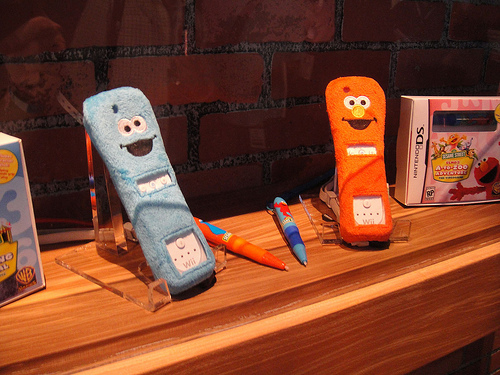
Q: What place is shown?
A: It is a display.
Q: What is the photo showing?
A: It is showing a display.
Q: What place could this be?
A: It is a display.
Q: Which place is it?
A: It is a display.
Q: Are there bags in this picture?
A: No, there are no bags.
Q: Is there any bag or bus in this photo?
A: No, there are no bags or buses.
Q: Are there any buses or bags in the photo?
A: No, there are no bags or buses.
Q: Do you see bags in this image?
A: No, there are no bags.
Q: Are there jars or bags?
A: No, there are no bags or jars.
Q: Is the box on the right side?
A: Yes, the box is on the right of the image.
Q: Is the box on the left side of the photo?
A: No, the box is on the right of the image.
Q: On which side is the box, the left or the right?
A: The box is on the right of the image.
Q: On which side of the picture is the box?
A: The box is on the right of the image.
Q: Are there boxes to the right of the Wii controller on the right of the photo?
A: Yes, there is a box to the right of the Wii remotes.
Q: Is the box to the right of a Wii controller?
A: Yes, the box is to the right of a Wii controller.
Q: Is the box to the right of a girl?
A: No, the box is to the right of a Wii controller.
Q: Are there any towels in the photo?
A: No, there are no towels.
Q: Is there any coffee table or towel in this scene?
A: No, there are no towels or coffee tables.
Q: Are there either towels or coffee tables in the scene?
A: No, there are no towels or coffee tables.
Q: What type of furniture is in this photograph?
A: The furniture is a shelf.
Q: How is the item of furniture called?
A: The piece of furniture is a shelf.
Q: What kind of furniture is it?
A: The piece of furniture is a shelf.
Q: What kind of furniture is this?
A: This is a shelf.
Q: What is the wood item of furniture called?
A: The piece of furniture is a shelf.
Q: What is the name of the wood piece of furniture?
A: The piece of furniture is a shelf.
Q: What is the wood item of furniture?
A: The piece of furniture is a shelf.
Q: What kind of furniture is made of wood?
A: The furniture is a shelf.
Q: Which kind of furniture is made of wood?
A: The furniture is a shelf.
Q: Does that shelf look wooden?
A: Yes, the shelf is wooden.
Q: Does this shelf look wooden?
A: Yes, the shelf is wooden.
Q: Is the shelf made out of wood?
A: Yes, the shelf is made of wood.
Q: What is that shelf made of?
A: The shelf is made of wood.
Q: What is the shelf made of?
A: The shelf is made of wood.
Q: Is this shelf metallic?
A: No, the shelf is wooden.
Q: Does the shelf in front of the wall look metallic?
A: No, the shelf is wooden.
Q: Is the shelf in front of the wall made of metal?
A: No, the shelf is made of wood.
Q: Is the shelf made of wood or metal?
A: The shelf is made of wood.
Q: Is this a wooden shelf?
A: Yes, this is a wooden shelf.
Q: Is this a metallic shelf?
A: No, this is a wooden shelf.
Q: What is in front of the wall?
A: The shelf is in front of the wall.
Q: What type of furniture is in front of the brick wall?
A: The piece of furniture is a shelf.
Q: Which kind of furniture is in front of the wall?
A: The piece of furniture is a shelf.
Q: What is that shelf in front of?
A: The shelf is in front of the wall.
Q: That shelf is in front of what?
A: The shelf is in front of the wall.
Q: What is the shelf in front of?
A: The shelf is in front of the wall.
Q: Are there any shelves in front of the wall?
A: Yes, there is a shelf in front of the wall.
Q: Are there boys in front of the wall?
A: No, there is a shelf in front of the wall.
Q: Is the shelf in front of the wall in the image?
A: Yes, the shelf is in front of the wall.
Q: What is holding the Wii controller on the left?
A: The shelf is holding the Wii controller.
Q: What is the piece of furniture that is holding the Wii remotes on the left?
A: The piece of furniture is a shelf.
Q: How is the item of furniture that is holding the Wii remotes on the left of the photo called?
A: The piece of furniture is a shelf.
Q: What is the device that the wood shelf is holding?
A: The device is a Wii controller.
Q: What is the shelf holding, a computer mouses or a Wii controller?
A: The shelf is holding a Wii controller.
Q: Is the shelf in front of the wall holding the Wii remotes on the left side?
A: Yes, the shelf is holding the Wii controller.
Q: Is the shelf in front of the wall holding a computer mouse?
A: No, the shelf is holding the Wii controller.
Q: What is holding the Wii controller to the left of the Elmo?
A: The shelf is holding the Wii controller.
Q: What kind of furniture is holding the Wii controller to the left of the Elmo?
A: The piece of furniture is a shelf.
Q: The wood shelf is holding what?
A: The shelf is holding the Wii controller.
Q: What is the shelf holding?
A: The shelf is holding the Wii controller.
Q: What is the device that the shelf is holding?
A: The device is a Wii controller.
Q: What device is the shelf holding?
A: The shelf is holding the Wii remotes.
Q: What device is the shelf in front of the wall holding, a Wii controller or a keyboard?
A: The shelf is holding a Wii controller.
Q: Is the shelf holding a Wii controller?
A: Yes, the shelf is holding a Wii controller.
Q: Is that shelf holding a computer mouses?
A: No, the shelf is holding a Wii controller.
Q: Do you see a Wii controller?
A: Yes, there is a Wii controller.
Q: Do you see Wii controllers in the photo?
A: Yes, there is a Wii controller.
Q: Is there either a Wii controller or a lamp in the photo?
A: Yes, there is a Wii controller.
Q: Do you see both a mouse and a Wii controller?
A: No, there is a Wii controller but no computer mice.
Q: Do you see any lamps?
A: No, there are no lamps.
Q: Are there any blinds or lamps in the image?
A: No, there are no lamps or blinds.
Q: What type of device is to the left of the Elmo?
A: The device is a Wii controller.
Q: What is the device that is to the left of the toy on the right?
A: The device is a Wii controller.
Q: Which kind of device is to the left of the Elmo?
A: The device is a Wii controller.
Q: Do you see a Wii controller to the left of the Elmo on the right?
A: Yes, there is a Wii controller to the left of the Elmo.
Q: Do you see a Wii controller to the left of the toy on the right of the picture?
A: Yes, there is a Wii controller to the left of the Elmo.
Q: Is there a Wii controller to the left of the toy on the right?
A: Yes, there is a Wii controller to the left of the Elmo.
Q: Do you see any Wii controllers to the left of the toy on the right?
A: Yes, there is a Wii controller to the left of the Elmo.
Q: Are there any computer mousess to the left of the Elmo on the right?
A: No, there is a Wii controller to the left of the Elmo.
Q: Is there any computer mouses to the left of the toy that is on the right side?
A: No, there is a Wii controller to the left of the Elmo.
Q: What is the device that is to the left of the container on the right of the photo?
A: The device is a Wii controller.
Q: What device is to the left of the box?
A: The device is a Wii controller.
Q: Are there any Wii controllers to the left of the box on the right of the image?
A: Yes, there is a Wii controller to the left of the box.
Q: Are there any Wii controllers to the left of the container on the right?
A: Yes, there is a Wii controller to the left of the box.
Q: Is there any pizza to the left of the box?
A: No, there is a Wii controller to the left of the box.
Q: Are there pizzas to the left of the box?
A: No, there is a Wii controller to the left of the box.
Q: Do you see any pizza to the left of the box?
A: No, there is a Wii controller to the left of the box.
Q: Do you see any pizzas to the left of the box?
A: No, there is a Wii controller to the left of the box.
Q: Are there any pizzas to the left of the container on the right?
A: No, there is a Wii controller to the left of the box.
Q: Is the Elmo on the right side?
A: Yes, the Elmo is on the right of the image.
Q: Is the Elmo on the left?
A: No, the Elmo is on the right of the image.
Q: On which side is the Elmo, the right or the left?
A: The Elmo is on the right of the image.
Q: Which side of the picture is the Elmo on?
A: The Elmo is on the right of the image.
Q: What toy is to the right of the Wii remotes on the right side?
A: The toy is an Elmo.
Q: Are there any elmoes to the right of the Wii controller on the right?
A: Yes, there is an Elmo to the right of the Wii remotes.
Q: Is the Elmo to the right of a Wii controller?
A: Yes, the Elmo is to the right of a Wii controller.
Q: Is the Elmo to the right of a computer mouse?
A: No, the Elmo is to the right of a Wii controller.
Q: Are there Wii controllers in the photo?
A: Yes, there is a Wii controller.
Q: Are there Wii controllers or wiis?
A: Yes, there is a Wii controller.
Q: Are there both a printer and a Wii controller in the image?
A: No, there is a Wii controller but no printers.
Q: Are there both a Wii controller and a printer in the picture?
A: No, there is a Wii controller but no printers.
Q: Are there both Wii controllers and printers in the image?
A: No, there is a Wii controller but no printers.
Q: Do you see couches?
A: No, there are no couches.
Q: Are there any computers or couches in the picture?
A: No, there are no couches or computers.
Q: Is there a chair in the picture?
A: No, there are no chairs.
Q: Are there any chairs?
A: No, there are no chairs.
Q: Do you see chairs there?
A: No, there are no chairs.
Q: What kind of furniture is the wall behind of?
A: The wall is behind the shelf.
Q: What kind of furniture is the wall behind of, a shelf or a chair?
A: The wall is behind a shelf.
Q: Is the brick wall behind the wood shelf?
A: Yes, the wall is behind the shelf.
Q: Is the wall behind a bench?
A: No, the wall is behind the shelf.